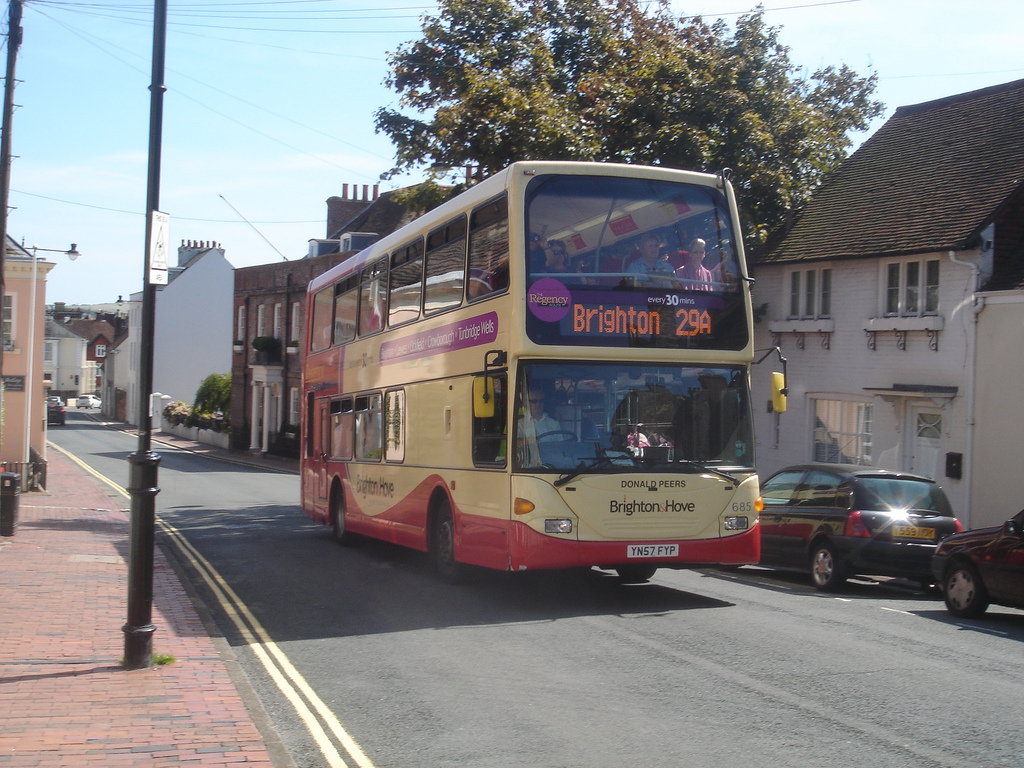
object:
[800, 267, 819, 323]
window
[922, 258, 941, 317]
window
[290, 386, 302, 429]
window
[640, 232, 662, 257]
head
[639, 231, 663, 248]
man hair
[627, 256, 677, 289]
shirt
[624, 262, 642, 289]
arm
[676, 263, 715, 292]
man shirt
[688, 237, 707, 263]
man head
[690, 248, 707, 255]
glasses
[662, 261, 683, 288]
man arms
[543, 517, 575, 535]
bus headlight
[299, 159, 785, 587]
bus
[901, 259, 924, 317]
window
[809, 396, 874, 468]
window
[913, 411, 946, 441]
window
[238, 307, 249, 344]
window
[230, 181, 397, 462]
building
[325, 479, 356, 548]
wheel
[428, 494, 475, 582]
wheel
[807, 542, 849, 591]
wheel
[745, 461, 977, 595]
car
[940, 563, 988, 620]
wheel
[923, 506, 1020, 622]
car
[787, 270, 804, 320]
window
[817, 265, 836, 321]
window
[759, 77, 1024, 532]
building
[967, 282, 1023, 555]
building